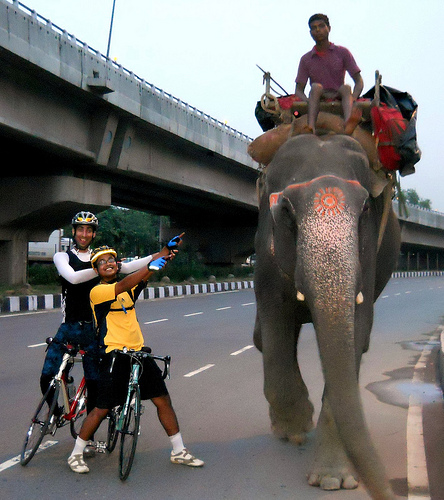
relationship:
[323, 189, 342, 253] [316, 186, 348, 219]
small circular orange patterned disk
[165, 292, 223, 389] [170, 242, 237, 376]
portion of white broken line on road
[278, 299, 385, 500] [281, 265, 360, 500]
large gray elephant tusk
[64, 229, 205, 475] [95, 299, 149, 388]
man's black and orange biking shirt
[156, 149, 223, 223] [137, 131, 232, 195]
portion of highway overpass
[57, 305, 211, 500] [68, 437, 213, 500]
man's gray and white sneakers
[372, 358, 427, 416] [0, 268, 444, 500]
spot on road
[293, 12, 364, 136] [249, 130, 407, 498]
man on elephant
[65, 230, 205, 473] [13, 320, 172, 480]
boy on bicycles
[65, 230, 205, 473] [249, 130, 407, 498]
boy pointing elephant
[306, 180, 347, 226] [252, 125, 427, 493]
marking on elephant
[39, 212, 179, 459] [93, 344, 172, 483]
boy on bicycle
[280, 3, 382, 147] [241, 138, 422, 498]
man on an elephant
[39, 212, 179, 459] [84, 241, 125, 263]
boy wearing helmet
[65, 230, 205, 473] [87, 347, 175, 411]
boy wearing shorts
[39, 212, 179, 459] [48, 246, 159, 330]
boy wearing shirt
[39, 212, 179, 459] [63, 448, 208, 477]
boy wearing shoes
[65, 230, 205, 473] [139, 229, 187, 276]
boy wearing gloves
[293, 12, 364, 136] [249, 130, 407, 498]
man riding on a elephant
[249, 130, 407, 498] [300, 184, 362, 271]
elephant with face paint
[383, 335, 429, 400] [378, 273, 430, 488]
puddles on road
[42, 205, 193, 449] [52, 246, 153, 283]
boy wearing shirt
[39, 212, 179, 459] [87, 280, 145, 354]
boy wearing shirt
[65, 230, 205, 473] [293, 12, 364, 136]
boy pointing at man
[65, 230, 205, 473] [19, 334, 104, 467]
boy on bicycle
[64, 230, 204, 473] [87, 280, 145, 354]
boy wearing shirt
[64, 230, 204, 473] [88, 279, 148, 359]
boy wearing shirt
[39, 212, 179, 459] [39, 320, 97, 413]
boy wearing pants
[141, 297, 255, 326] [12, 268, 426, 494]
dividers in road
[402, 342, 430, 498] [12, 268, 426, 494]
line at road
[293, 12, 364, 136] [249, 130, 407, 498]
man on an elephant